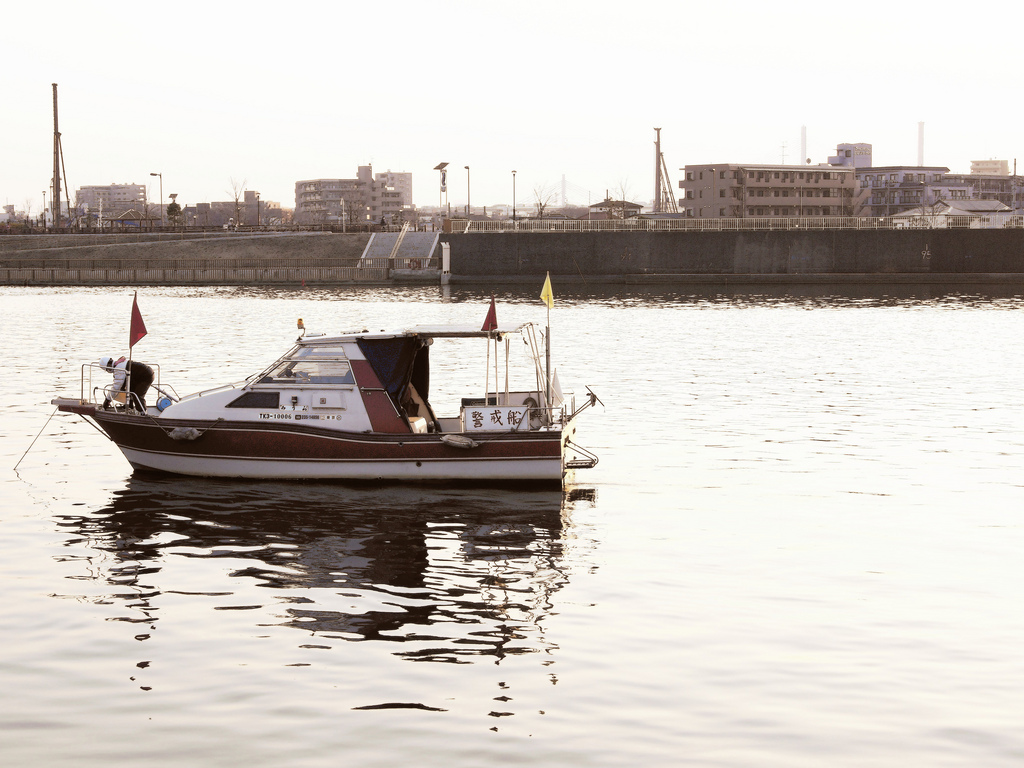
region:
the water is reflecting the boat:
[48, 456, 619, 713]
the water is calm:
[147, 465, 907, 725]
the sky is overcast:
[0, 19, 885, 212]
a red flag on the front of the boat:
[93, 253, 160, 424]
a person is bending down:
[51, 336, 191, 426]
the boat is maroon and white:
[61, 279, 580, 510]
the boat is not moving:
[36, 124, 666, 611]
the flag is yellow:
[519, 247, 578, 372]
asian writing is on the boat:
[435, 380, 541, 460]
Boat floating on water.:
[66, 284, 605, 487]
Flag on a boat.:
[117, 288, 159, 409]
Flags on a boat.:
[470, 247, 589, 437]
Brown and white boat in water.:
[66, 322, 591, 499]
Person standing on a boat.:
[98, 348, 155, 419]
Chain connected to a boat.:
[13, 401, 61, 482]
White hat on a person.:
[95, 353, 122, 374]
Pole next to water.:
[41, 80, 89, 232]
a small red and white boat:
[58, 326, 594, 491]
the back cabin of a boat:
[385, 332, 551, 438]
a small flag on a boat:
[123, 286, 144, 401]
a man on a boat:
[96, 355, 151, 403]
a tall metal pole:
[43, 86, 63, 222]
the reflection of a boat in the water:
[63, 465, 592, 731]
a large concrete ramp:
[356, 228, 448, 273]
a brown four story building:
[679, 159, 856, 235]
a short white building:
[890, 175, 1011, 233]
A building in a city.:
[688, 165, 879, 220]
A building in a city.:
[300, 172, 402, 227]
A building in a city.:
[73, 178, 147, 220]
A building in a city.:
[379, 168, 422, 204]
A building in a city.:
[831, 141, 866, 158]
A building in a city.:
[885, 163, 1019, 208]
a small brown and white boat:
[30, 271, 603, 493]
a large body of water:
[0, 275, 1021, 766]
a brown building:
[677, 160, 864, 214]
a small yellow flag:
[542, 259, 561, 307]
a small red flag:
[124, 301, 154, 352]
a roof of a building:
[943, 193, 1008, 210]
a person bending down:
[98, 351, 157, 410]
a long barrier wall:
[441, 225, 1018, 268]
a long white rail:
[457, 215, 906, 229]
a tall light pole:
[147, 167, 170, 216]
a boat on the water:
[78, 289, 600, 509]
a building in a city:
[68, 178, 161, 224]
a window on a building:
[743, 171, 753, 179]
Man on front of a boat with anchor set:
[13, 265, 603, 537]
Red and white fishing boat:
[48, 268, 624, 502]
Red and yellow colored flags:
[475, 256, 561, 406]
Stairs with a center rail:
[345, 211, 457, 291]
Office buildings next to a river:
[4, 78, 1022, 317]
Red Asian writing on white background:
[466, 405, 530, 435]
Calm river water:
[0, 274, 1022, 766]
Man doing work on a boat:
[83, 348, 167, 421]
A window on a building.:
[717, 168, 725, 182]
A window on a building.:
[717, 187, 733, 201]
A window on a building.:
[740, 187, 754, 197]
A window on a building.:
[830, 181, 843, 198]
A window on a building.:
[932, 185, 946, 202]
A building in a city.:
[669, 153, 854, 218]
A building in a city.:
[860, 168, 930, 203]